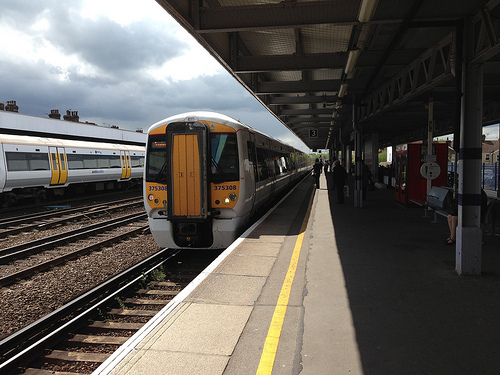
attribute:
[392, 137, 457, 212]
vending machine — red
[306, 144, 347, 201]
people — standing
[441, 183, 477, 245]
woman — sitting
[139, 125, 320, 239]
train — yellow, white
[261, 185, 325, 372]
line — yellow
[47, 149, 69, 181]
doors — white, yellow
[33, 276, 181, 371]
planks — wooden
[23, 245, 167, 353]
rods — steel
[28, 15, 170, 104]
sky — grey, cloudy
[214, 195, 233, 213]
light — small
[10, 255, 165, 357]
tracks — close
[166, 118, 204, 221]
doors — yellow